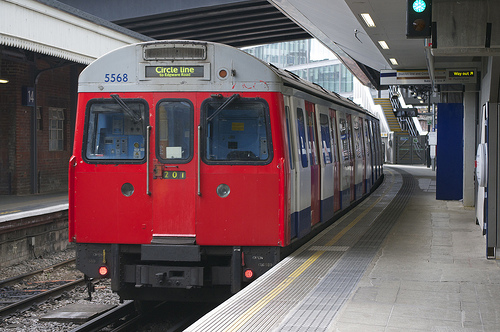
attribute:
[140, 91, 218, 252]
door — entrance door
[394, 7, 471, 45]
traffic signal — small, green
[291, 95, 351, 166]
side windows — clear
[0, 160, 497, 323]
train station — empty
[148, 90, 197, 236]
door — red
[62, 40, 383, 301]
train — grey, red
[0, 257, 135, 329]
tracks — brown, metal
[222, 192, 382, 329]
yellow line — painted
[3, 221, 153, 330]
line — railway 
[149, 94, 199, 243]
door — to exit train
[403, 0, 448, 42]
light — lit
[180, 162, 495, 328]
walkway — leading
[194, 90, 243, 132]
wiper — black , metal, wind, shield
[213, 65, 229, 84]
lights — red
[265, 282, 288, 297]
lines — yellow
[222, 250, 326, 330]
lines — yellow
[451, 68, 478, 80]
sign — digital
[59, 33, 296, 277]
front — red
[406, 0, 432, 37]
light — green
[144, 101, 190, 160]
window — clear, closed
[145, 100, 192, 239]
door — closed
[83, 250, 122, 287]
light — red, small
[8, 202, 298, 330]
tracks — train tracks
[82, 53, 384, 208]
train — red, white, blue